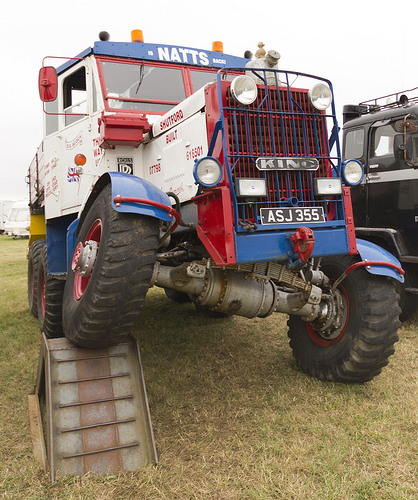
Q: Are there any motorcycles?
A: No, there are no motorcycles.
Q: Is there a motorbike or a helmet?
A: No, there are no motorcycles or helmets.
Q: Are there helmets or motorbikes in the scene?
A: No, there are no motorbikes or helmets.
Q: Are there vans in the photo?
A: No, there are no vans.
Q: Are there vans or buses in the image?
A: No, there are no vans or buses.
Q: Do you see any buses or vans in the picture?
A: No, there are no vans or buses.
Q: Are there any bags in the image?
A: No, there are no bags.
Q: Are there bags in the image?
A: No, there are no bags.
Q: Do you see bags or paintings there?
A: No, there are no bags or paintings.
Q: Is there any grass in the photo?
A: Yes, there is grass.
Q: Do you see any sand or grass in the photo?
A: Yes, there is grass.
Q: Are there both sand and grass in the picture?
A: No, there is grass but no sand.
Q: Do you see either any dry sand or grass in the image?
A: Yes, there is dry grass.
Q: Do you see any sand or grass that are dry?
A: Yes, the grass is dry.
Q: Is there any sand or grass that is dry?
A: Yes, the grass is dry.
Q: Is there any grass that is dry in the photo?
A: Yes, there is dry grass.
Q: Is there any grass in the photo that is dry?
A: Yes, there is grass that is dry.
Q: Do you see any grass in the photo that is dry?
A: Yes, there is grass that is dry.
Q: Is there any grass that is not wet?
A: Yes, there is dry grass.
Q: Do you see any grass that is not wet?
A: Yes, there is dry grass.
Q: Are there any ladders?
A: No, there are no ladders.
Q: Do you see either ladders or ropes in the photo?
A: No, there are no ladders or ropes.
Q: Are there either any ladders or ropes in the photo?
A: No, there are no ladders or ropes.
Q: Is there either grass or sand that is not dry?
A: No, there is grass but it is dry.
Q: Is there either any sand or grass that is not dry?
A: No, there is grass but it is dry.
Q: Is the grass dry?
A: Yes, the grass is dry.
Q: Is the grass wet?
A: No, the grass is dry.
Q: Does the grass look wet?
A: No, the grass is dry.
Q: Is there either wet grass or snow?
A: No, there is grass but it is dry.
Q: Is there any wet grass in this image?
A: No, there is grass but it is dry.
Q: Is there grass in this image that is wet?
A: No, there is grass but it is dry.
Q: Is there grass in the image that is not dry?
A: No, there is grass but it is dry.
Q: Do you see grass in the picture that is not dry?
A: No, there is grass but it is dry.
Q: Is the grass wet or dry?
A: The grass is dry.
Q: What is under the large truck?
A: The grass is under the truck.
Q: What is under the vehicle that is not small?
A: The grass is under the truck.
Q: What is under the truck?
A: The grass is under the truck.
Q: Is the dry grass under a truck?
A: Yes, the grass is under a truck.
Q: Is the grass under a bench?
A: No, the grass is under a truck.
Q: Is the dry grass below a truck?
A: Yes, the grass is below a truck.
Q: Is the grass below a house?
A: No, the grass is below a truck.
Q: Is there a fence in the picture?
A: No, there are no fences.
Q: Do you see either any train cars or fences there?
A: No, there are no fences or train cars.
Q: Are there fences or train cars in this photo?
A: No, there are no fences or train cars.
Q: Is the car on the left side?
A: No, the car is on the right of the image.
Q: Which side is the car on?
A: The car is on the right of the image.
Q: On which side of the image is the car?
A: The car is on the right of the image.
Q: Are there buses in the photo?
A: No, there are no buses.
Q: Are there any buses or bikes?
A: No, there are no buses or bikes.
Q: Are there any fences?
A: No, there are no fences.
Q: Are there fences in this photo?
A: No, there are no fences.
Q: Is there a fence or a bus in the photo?
A: No, there are no fences or buses.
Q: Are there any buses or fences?
A: No, there are no fences or buses.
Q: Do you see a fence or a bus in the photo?
A: No, there are no fences or buses.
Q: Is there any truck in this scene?
A: Yes, there is a truck.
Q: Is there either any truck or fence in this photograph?
A: Yes, there is a truck.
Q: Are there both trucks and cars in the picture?
A: Yes, there are both a truck and a car.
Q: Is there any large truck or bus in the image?
A: Yes, there is a large truck.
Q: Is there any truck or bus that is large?
A: Yes, the truck is large.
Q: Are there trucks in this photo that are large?
A: Yes, there is a large truck.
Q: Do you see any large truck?
A: Yes, there is a large truck.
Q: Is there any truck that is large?
A: Yes, there is a truck that is large.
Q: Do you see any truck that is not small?
A: Yes, there is a large truck.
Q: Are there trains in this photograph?
A: No, there are no trains.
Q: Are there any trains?
A: No, there are no trains.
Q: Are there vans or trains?
A: No, there are no trains or vans.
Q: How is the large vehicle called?
A: The vehicle is a truck.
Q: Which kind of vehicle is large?
A: The vehicle is a truck.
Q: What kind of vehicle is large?
A: The vehicle is a truck.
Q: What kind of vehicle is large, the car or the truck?
A: The truck is large.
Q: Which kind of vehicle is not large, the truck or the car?
A: The car is not large.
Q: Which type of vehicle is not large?
A: The vehicle is a car.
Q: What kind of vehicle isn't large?
A: The vehicle is a car.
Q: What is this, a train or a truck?
A: This is a truck.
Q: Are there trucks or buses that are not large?
A: No, there is a truck but it is large.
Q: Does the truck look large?
A: Yes, the truck is large.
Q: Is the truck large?
A: Yes, the truck is large.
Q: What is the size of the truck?
A: The truck is large.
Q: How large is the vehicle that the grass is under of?
A: The truck is large.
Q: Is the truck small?
A: No, the truck is large.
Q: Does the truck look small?
A: No, the truck is large.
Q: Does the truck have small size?
A: No, the truck is large.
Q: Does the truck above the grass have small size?
A: No, the truck is large.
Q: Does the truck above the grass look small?
A: No, the truck is large.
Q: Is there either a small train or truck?
A: No, there is a truck but it is large.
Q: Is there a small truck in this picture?
A: No, there is a truck but it is large.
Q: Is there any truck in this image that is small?
A: No, there is a truck but it is large.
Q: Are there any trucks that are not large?
A: No, there is a truck but it is large.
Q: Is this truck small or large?
A: The truck is large.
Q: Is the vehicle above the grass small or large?
A: The truck is large.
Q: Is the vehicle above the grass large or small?
A: The truck is large.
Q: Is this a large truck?
A: Yes, this is a large truck.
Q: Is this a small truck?
A: No, this is a large truck.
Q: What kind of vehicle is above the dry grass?
A: The vehicle is a truck.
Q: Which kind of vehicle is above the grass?
A: The vehicle is a truck.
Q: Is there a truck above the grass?
A: Yes, there is a truck above the grass.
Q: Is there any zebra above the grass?
A: No, there is a truck above the grass.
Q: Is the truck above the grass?
A: Yes, the truck is above the grass.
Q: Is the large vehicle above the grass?
A: Yes, the truck is above the grass.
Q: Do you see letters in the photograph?
A: Yes, there are letters.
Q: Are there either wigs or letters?
A: Yes, there are letters.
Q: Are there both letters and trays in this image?
A: No, there are letters but no trays.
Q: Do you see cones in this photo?
A: No, there are no cones.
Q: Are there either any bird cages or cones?
A: No, there are no cones or bird cages.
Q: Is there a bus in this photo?
A: No, there are no buses.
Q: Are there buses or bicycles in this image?
A: No, there are no buses or bicycles.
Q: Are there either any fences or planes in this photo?
A: No, there are no fences or planes.